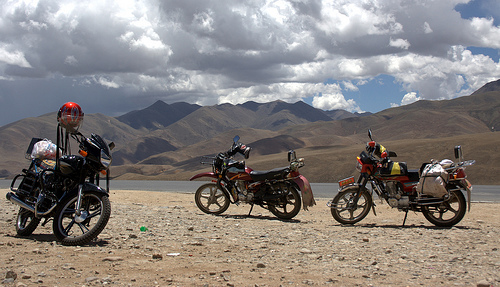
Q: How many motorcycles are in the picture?
A: Three.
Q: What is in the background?
A: Mountains.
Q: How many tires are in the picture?
A: Six.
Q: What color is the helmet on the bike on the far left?
A: Red.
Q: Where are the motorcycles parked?
A: In front of the mountains.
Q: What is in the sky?
A: Clouds.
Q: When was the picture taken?
A: During the day.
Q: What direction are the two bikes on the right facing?
A: Left.